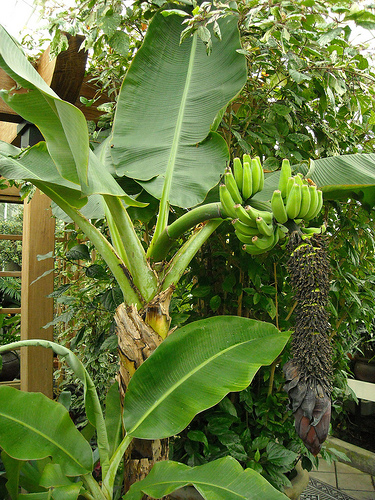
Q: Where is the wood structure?
A: On left.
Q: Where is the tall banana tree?
A: On right.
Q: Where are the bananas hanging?
A: On tree.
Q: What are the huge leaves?
A: Banana leaves.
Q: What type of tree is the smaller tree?
A: Banana.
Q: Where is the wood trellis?
A: Slight left.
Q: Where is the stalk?
A: On banana tree.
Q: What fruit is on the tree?
A: Banana.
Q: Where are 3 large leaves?
A: On dwarf plant.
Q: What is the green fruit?
A: Bananas.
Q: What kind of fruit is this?
A: Plantains.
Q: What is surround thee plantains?
A: Leaves.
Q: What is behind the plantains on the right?
A: Palm tree trunk.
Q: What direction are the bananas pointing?
A: Upward.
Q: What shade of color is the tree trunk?
A: Brown.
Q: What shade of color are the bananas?
A: Green.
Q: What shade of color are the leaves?
A: Green.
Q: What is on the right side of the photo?
A: Cement walkway.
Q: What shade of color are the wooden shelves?
A: Tan.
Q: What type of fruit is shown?
A: Bananas.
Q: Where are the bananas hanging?
A: Tree.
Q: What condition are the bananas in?
A: Green.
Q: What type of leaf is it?
A: Banana.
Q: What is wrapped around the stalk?
A: Leaves.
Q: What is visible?
A: Bananas.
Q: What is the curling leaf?
A: A banana leaf.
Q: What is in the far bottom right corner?
A: A tile floor.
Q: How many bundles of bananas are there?
A: One.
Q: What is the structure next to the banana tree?
A: Wooden post.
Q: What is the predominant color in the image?
A: Green.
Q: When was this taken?
A: During the day.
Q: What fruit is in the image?
A: Bananas.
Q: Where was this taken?
A: In a garden.